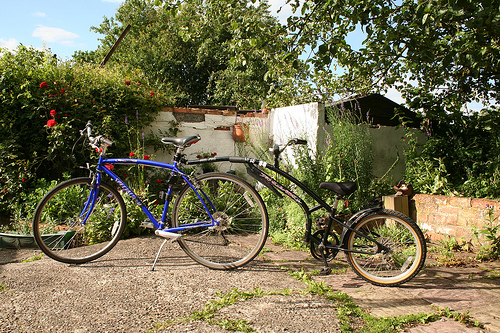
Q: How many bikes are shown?
A: Two.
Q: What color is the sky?
A: Blue.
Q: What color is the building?
A: White.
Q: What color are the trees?
A: Green.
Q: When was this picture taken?
A: Daytime.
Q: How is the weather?
A: Clear.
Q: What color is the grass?
A: Green.